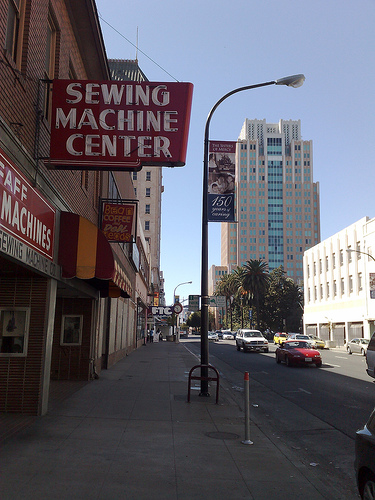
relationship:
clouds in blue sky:
[172, 231, 195, 274] [95, 1, 373, 306]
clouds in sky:
[184, 20, 293, 101] [0, 1, 374, 328]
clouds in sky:
[292, 109, 346, 142] [299, 27, 364, 65]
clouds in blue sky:
[184, 51, 237, 84] [95, 1, 374, 306]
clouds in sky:
[308, 31, 373, 65] [232, 22, 305, 65]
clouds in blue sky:
[237, 32, 280, 51] [95, 1, 374, 306]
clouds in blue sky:
[285, 27, 329, 61] [95, 1, 374, 306]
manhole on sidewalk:
[181, 420, 250, 450] [19, 311, 329, 497]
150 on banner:
[211, 195, 232, 206] [206, 139, 236, 220]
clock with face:
[172, 300, 184, 315] [168, 299, 185, 316]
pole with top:
[242, 366, 255, 444] [237, 369, 256, 383]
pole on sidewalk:
[242, 366, 255, 444] [1, 325, 295, 499]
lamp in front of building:
[333, 233, 373, 274] [301, 216, 373, 354]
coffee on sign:
[97, 204, 132, 248] [54, 60, 187, 172]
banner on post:
[206, 140, 238, 222] [176, 57, 315, 408]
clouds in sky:
[327, 89, 361, 155] [309, 87, 361, 199]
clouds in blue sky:
[325, 57, 365, 142] [95, 1, 374, 306]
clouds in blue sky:
[336, 83, 366, 146] [95, 1, 374, 306]